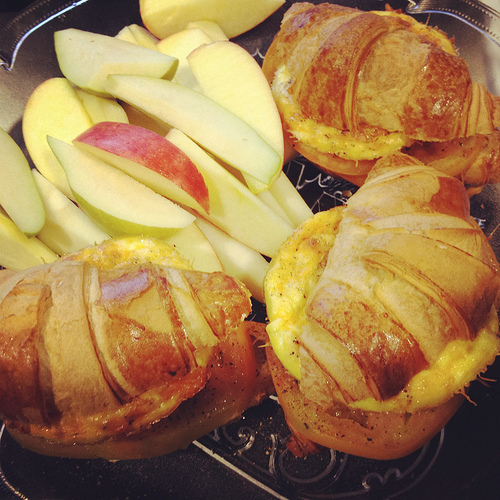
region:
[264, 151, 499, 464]
Croissant egg sandwich cooking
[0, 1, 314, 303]
Sliced apples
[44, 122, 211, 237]
Red and green skinned apple slices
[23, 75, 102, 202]
Yellowing apple slice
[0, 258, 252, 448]
Bacon cooking under croissant top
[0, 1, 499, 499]
Clear bowl with sandwiches and apple slices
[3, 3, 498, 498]
Platter of sandwiches and apples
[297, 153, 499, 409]
Shaped and baked croissant top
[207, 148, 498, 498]
Round cooking grates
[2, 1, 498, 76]
Rounded platter perimeter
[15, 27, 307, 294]
the apples are cut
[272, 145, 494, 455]
the croissants are cut in half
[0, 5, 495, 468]
three croissants sandwiches shown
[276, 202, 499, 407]
the sandwiches have eggs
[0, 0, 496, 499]
three sandwiches next to apples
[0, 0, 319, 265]
apples are green and red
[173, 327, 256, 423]
the vegetable has black pepper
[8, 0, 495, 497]
the photo is of food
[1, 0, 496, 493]
the food is in plastic container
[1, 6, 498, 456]
the sandwiches have many things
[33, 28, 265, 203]
the apple is sliced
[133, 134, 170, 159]
the apple is red in color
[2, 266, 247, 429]
this is a fried beef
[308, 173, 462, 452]
the beef is yummy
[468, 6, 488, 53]
this is a tray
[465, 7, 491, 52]
the tray is metallic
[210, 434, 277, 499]
the tray is shiny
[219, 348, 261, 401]
the beef is creamy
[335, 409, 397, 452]
this is a burger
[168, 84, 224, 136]
the apple is small in size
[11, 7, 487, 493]
a plate of food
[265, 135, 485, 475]
a breakfast sandwich on the plate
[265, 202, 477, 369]
egg is on the sandwich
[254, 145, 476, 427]
a croissant bread on top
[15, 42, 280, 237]
a bunch of apples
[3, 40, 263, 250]
the apples are sliced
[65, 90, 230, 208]
the skin is red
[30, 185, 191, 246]
the apple skin is green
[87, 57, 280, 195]
inside of the apple is white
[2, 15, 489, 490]
the plate is glass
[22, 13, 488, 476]
breakfast on a platter with apples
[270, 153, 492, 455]
breakfast on a platter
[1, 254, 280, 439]
breakfast on a platter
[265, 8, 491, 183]
breakfast on a platter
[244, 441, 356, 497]
platter under the breakfast sandwiches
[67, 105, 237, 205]
slice of red apple on platter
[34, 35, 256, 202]
bunch of sliced apples